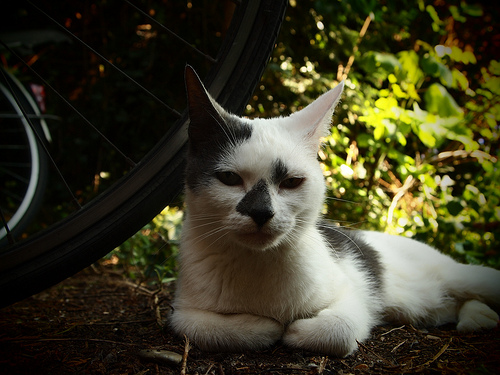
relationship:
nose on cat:
[243, 207, 279, 220] [170, 63, 500, 360]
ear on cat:
[296, 76, 347, 146] [170, 63, 500, 360]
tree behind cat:
[123, 0, 500, 229] [170, 63, 500, 360]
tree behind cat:
[350, 34, 406, 229] [163, 78, 343, 286]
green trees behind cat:
[374, 65, 463, 171] [170, 63, 500, 360]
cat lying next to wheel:
[155, 88, 406, 285] [8, 7, 280, 315]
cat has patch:
[170, 63, 500, 360] [230, 174, 285, 226]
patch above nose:
[230, 174, 285, 226] [243, 202, 277, 221]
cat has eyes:
[170, 63, 500, 360] [212, 170, 308, 190]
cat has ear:
[170, 63, 500, 360] [177, 59, 246, 166]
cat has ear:
[170, 63, 500, 360] [281, 70, 351, 153]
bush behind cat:
[0, 0, 500, 287] [170, 63, 500, 360]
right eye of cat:
[211, 170, 241, 187] [170, 63, 500, 360]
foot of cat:
[454, 297, 487, 326] [170, 63, 500, 360]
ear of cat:
[296, 82, 348, 145] [170, 63, 500, 360]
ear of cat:
[180, 60, 238, 150] [170, 63, 500, 360]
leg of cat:
[173, 305, 282, 357] [170, 63, 500, 360]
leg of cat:
[277, 293, 374, 350] [170, 63, 500, 360]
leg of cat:
[453, 292, 488, 337] [170, 63, 500, 360]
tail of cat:
[447, 251, 499, 301] [170, 63, 500, 360]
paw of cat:
[448, 284, 498, 336] [170, 63, 500, 360]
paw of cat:
[283, 316, 321, 352] [170, 63, 500, 360]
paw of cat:
[236, 310, 281, 349] [170, 63, 500, 360]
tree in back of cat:
[123, 0, 500, 229] [170, 63, 500, 360]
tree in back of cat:
[123, 0, 500, 229] [118, 51, 497, 356]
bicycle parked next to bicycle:
[11, 14, 291, 297] [0, 50, 84, 230]